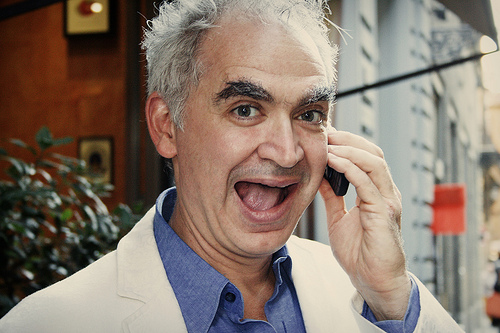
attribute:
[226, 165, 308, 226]
mouth — open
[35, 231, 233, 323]
jacket — white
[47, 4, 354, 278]
gentleman — older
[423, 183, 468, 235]
banner — small, orange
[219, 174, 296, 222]
tongue — showing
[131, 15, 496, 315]
man — black, white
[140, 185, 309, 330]
shirt — blue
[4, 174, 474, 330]
jacket — white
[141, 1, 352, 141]
hair — gray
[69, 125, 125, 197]
frame — black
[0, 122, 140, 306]
plant — green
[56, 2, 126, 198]
pictures — framed 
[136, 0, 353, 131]
hair — gray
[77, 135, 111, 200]
art — framed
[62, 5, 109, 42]
art — framed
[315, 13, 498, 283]
building — gray 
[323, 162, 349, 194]
cellphone — small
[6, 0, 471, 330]
man — happy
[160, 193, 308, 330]
shirt — blue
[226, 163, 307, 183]
mustache — gray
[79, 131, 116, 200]
picture — framed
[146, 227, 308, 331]
man's shirt — blue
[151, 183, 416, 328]
shirt — light, button down, blue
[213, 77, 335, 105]
eyebrows — bushy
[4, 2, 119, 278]
panaling — wood